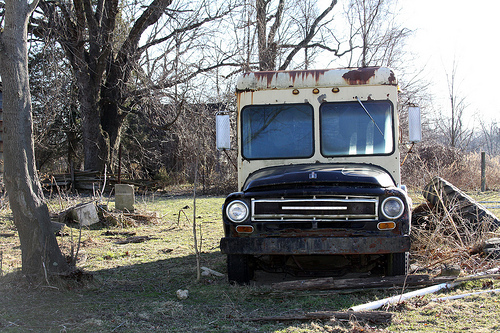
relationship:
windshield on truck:
[318, 98, 394, 160] [225, 72, 414, 278]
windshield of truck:
[239, 99, 317, 163] [225, 72, 414, 278]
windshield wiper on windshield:
[351, 94, 389, 138] [318, 98, 394, 160]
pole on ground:
[347, 282, 455, 313] [29, 198, 464, 331]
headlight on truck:
[381, 191, 407, 229] [225, 72, 414, 278]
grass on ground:
[144, 283, 175, 321] [29, 198, 464, 331]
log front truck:
[267, 273, 434, 291] [225, 72, 414, 278]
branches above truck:
[283, 0, 400, 56] [225, 72, 414, 278]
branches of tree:
[283, 0, 400, 56] [252, 4, 294, 74]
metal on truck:
[355, 71, 366, 76] [225, 72, 414, 278]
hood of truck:
[247, 164, 394, 186] [225, 72, 414, 278]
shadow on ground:
[34, 258, 332, 331] [29, 198, 464, 331]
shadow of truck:
[34, 258, 332, 331] [225, 72, 414, 278]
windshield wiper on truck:
[351, 94, 389, 138] [225, 72, 414, 278]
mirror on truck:
[408, 103, 426, 149] [225, 72, 414, 278]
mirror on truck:
[209, 114, 235, 148] [225, 72, 414, 278]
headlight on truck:
[225, 199, 247, 224] [225, 72, 414, 278]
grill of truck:
[254, 198, 382, 223] [225, 72, 414, 278]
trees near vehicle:
[14, 3, 382, 71] [225, 72, 414, 278]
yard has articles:
[12, 167, 230, 320] [240, 272, 471, 333]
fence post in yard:
[347, 282, 455, 313] [12, 167, 230, 320]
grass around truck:
[144, 283, 175, 321] [225, 72, 414, 278]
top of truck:
[237, 68, 404, 86] [225, 72, 414, 278]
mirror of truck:
[408, 103, 426, 149] [225, 72, 414, 278]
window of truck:
[318, 98, 394, 160] [225, 72, 414, 278]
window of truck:
[239, 99, 317, 163] [225, 72, 414, 278]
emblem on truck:
[304, 170, 321, 184] [225, 72, 414, 278]